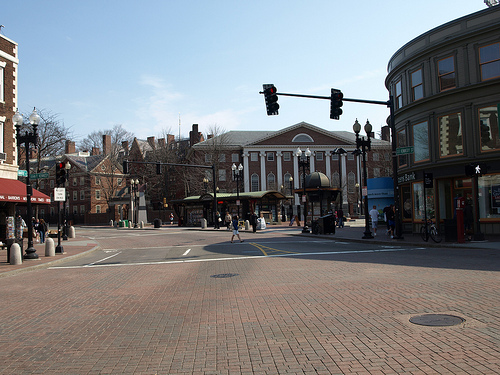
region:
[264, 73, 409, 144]
street lights are red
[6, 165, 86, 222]
red canopy over doors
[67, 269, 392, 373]
road is made of bricks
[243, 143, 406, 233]
pillars on the front of building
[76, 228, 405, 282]
pedestrian walkway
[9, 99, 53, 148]
two street lights on one pole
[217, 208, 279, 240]
person in the crosswalk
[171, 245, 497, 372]
two manholes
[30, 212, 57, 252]
person walking on sidewalk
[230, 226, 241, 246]
person wearing white shorts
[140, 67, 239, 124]
White clouds in the sky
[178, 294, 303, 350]
Bricks on the ground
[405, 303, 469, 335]
Pothole on the ground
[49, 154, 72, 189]
Traffic light is lit up red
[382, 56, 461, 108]
Windows on a building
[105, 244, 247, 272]
White lines on the ground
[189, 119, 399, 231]
A large brown and white building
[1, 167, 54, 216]
A red awning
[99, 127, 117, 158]
Chimney on a roof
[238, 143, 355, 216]
White columns in front of building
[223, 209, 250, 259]
Person is walking in the street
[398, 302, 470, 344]
A sewer is in the foreground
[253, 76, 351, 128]
Two traffic lights are in view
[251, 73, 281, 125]
Traffic light is on red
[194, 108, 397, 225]
A building is in the background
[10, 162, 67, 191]
Two green street signs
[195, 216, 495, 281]
Building is casting a shadow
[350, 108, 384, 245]
A street lamp in the background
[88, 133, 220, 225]
Trees in the background are bare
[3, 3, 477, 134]
The sky is clear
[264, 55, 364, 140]
two black traffic lights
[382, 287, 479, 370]
black manhole cover on street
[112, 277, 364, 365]
street is brick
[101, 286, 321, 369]
street's bricks are red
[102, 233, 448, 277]
white crosswalk on street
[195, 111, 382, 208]
large building with white columns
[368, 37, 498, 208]
round building on right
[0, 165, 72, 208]
red awning on shop on left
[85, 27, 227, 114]
sky is blue and mostly clear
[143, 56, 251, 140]
few clouds in sky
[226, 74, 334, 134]
the light is red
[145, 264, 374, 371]
the street is made of bricks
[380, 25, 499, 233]
the building is curved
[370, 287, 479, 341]
a man hole on the street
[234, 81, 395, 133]
the traffic light is attached to the building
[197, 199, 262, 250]
woman crossing the street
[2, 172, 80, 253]
a store on the corner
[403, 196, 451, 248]
a bike parked on the sidewalk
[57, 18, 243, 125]
the sky is partly cloudy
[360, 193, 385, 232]
man in a white t shirt walking